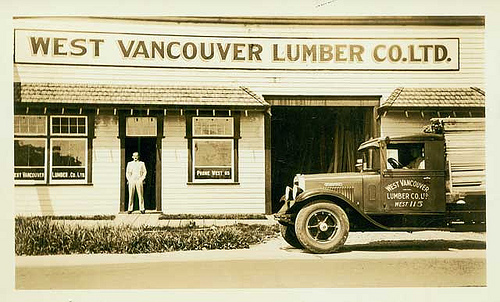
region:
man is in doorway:
[101, 141, 152, 203]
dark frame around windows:
[185, 114, 232, 195]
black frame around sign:
[11, 33, 452, 75]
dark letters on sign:
[5, 21, 446, 101]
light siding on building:
[10, 47, 487, 97]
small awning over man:
[25, 70, 277, 108]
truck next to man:
[271, 107, 479, 285]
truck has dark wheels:
[258, 210, 378, 265]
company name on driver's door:
[362, 167, 439, 238]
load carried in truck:
[414, 114, 481, 218]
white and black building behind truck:
[11, 15, 486, 220]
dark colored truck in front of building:
[270, 115, 487, 250]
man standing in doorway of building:
[125, 150, 145, 211]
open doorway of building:
[120, 135, 155, 210]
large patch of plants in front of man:
[15, 215, 271, 255]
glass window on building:
[185, 110, 235, 185]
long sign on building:
[12, 26, 457, 67]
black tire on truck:
[290, 200, 345, 250]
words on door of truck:
[385, 176, 427, 206]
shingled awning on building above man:
[12, 81, 267, 114]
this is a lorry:
[273, 124, 474, 232]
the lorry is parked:
[263, 120, 485, 245]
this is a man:
[120, 143, 155, 213]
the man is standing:
[118, 141, 155, 206]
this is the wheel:
[295, 206, 349, 241]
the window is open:
[385, 140, 427, 172]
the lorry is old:
[363, 175, 387, 206]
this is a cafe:
[175, 102, 263, 212]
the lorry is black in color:
[397, 178, 438, 205]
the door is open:
[123, 135, 153, 150]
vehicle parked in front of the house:
[278, 149, 474, 251]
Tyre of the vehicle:
[298, 205, 348, 247]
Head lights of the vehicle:
[281, 183, 302, 198]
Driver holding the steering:
[386, 143, 426, 175]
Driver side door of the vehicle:
[383, 174, 435, 205]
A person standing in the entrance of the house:
[123, 140, 158, 211]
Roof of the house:
[29, 78, 260, 105]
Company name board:
[31, 32, 452, 67]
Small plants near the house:
[21, 218, 221, 252]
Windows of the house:
[21, 115, 83, 180]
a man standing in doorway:
[117, 155, 162, 222]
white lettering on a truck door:
[384, 180, 440, 215]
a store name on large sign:
[12, 29, 463, 74]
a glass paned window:
[189, 117, 234, 184]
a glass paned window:
[49, 112, 88, 182]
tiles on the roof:
[383, 89, 488, 108]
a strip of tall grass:
[18, 216, 240, 251]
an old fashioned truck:
[267, 124, 488, 246]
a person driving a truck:
[403, 147, 428, 171]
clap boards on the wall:
[161, 117, 190, 212]